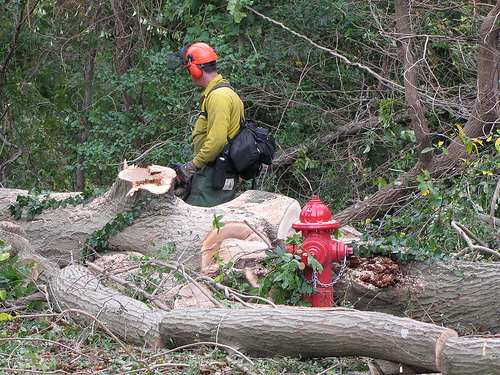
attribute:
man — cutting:
[176, 44, 251, 209]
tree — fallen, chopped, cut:
[6, 164, 499, 373]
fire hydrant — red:
[287, 190, 354, 307]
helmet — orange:
[181, 42, 219, 64]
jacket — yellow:
[192, 73, 244, 164]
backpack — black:
[232, 120, 277, 180]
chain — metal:
[312, 263, 347, 290]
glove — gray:
[178, 163, 198, 184]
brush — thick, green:
[4, 4, 499, 260]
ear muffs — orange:
[188, 64, 206, 81]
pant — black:
[189, 159, 234, 207]